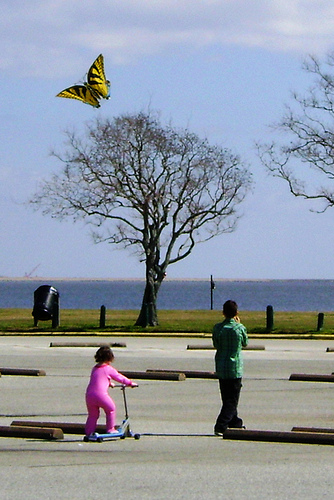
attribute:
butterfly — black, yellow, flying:
[47, 53, 127, 114]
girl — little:
[78, 338, 143, 447]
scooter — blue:
[82, 375, 146, 443]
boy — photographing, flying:
[205, 295, 263, 440]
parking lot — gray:
[3, 333, 332, 496]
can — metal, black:
[30, 284, 65, 327]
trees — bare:
[26, 39, 333, 329]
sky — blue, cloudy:
[0, 0, 333, 279]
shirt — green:
[204, 317, 254, 380]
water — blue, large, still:
[2, 278, 334, 309]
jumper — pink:
[82, 362, 126, 432]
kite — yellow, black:
[43, 51, 127, 115]